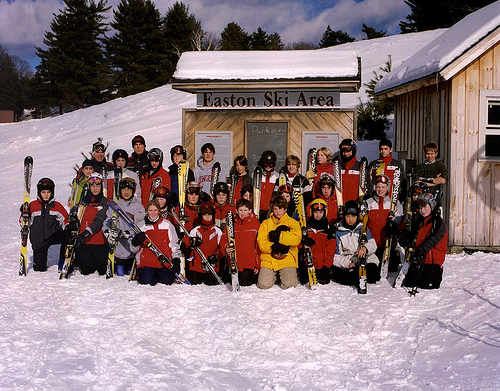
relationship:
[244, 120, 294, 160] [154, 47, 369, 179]
chalk board on building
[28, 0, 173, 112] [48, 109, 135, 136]
trees behind snow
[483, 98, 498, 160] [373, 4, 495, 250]
window on building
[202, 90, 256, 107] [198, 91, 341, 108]
easton in sign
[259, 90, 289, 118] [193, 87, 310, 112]
ski on sign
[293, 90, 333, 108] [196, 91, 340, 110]
word on sign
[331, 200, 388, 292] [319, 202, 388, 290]
skier wearing white jacket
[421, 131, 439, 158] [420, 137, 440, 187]
head on a child